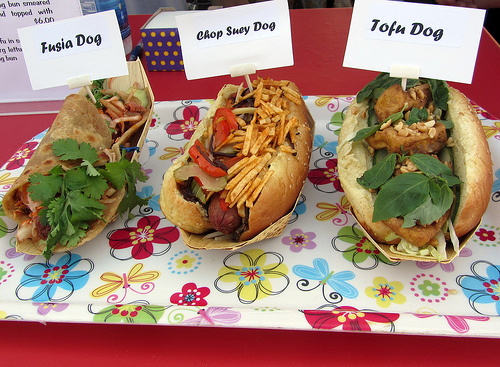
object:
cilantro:
[26, 137, 148, 261]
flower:
[106, 215, 181, 261]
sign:
[15, 10, 132, 92]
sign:
[174, 0, 295, 80]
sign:
[340, 0, 485, 86]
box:
[139, 6, 222, 72]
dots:
[140, 30, 184, 73]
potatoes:
[219, 81, 301, 218]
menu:
[1, 0, 85, 116]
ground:
[0, 320, 500, 367]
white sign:
[340, 0, 488, 84]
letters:
[39, 18, 445, 54]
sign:
[0, 0, 86, 119]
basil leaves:
[356, 144, 465, 228]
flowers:
[15, 250, 95, 303]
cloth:
[225, 252, 366, 325]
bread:
[158, 75, 314, 242]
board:
[0, 95, 500, 339]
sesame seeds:
[460, 89, 490, 205]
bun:
[336, 83, 494, 247]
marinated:
[369, 117, 446, 155]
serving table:
[0, 0, 499, 367]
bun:
[1, 89, 150, 252]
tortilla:
[6, 92, 116, 225]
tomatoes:
[191, 108, 240, 178]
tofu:
[380, 85, 441, 153]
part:
[386, 253, 400, 263]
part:
[244, 210, 254, 217]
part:
[242, 287, 264, 314]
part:
[407, 161, 421, 186]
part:
[147, 245, 250, 299]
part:
[0, 259, 92, 305]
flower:
[213, 250, 290, 304]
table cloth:
[0, 260, 269, 328]